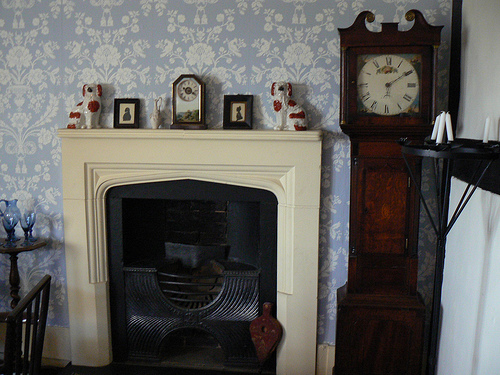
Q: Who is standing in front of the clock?
A: No one.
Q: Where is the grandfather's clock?
A: In the corner.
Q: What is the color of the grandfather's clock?
A: Brown.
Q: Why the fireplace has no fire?
A: It's not being used.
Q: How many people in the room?
A: No one.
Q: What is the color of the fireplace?
A: Black and beige.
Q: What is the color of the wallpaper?
A: Blue and white.